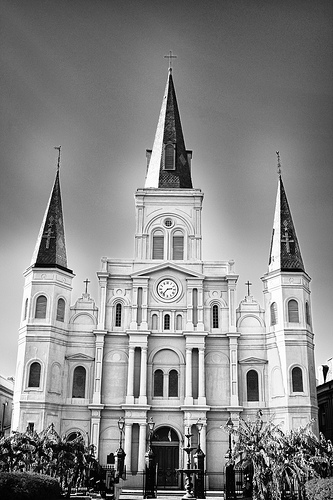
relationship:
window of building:
[153, 365, 175, 394] [4, 57, 318, 495]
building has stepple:
[8, 47, 322, 499] [141, 53, 195, 189]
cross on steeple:
[160, 43, 179, 64] [140, 64, 196, 188]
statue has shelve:
[171, 425, 204, 498] [177, 443, 197, 452]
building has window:
[4, 57, 318, 495] [68, 364, 87, 397]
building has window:
[4, 57, 318, 495] [26, 357, 41, 387]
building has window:
[4, 57, 318, 495] [149, 365, 163, 398]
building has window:
[4, 57, 318, 495] [166, 367, 180, 398]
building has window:
[4, 57, 318, 495] [244, 365, 260, 403]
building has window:
[4, 57, 318, 495] [287, 363, 305, 394]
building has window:
[4, 57, 318, 495] [161, 311, 170, 330]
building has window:
[4, 57, 318, 495] [211, 302, 220, 326]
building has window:
[4, 57, 318, 495] [285, 296, 300, 322]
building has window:
[4, 57, 318, 495] [131, 345, 143, 397]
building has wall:
[4, 57, 318, 495] [22, 333, 53, 356]